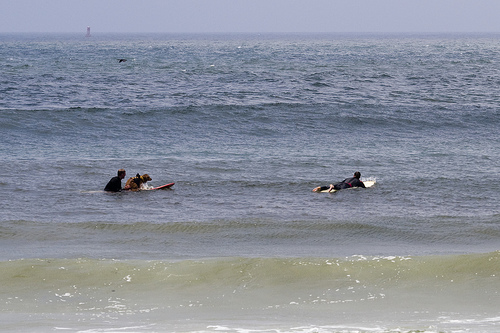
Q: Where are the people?
A: Ocean.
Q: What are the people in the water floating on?
A: Surfboard.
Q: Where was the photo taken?
A: Beach.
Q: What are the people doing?
A: Surfing.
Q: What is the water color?
A: Blue.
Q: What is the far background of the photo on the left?
A: Buoy.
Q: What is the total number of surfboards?
A: 2.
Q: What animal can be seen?
A: Dog.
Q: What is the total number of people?
A: 2.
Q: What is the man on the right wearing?
A: Wetsuit.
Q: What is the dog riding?
A: Surfboard.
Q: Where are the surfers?
A: In the water.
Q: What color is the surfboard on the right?
A: White.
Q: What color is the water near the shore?
A: Brown.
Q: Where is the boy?
A: In the background on the left hand side.